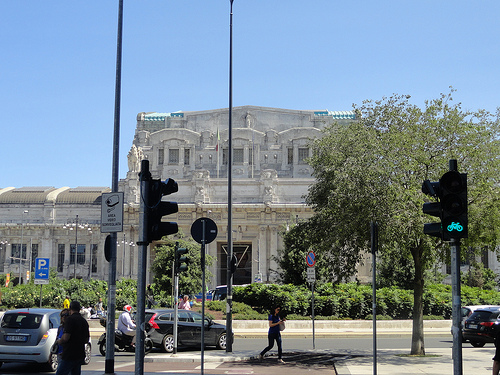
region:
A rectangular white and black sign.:
[98, 188, 129, 234]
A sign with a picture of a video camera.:
[95, 188, 125, 236]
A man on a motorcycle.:
[95, 305, 153, 357]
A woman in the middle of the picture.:
[255, 299, 299, 369]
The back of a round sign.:
[189, 210, 224, 250]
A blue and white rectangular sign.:
[31, 252, 48, 287]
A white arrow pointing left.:
[30, 260, 53, 284]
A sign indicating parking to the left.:
[27, 255, 49, 287]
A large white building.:
[3, 80, 490, 290]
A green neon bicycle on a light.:
[438, 211, 468, 238]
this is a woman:
[211, 281, 299, 334]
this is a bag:
[263, 276, 306, 367]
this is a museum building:
[213, 108, 271, 188]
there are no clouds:
[45, 109, 66, 122]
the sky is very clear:
[7, 97, 74, 172]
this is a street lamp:
[408, 155, 471, 232]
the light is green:
[434, 179, 481, 304]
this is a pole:
[410, 281, 490, 323]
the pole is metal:
[389, 304, 464, 371]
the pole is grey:
[431, 291, 468, 298]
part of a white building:
[1, 109, 378, 293]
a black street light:
[138, 165, 184, 252]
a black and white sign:
[98, 193, 123, 235]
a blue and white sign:
[30, 254, 50, 287]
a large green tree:
[306, 113, 498, 361]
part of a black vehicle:
[466, 305, 498, 344]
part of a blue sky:
[305, 0, 481, 58]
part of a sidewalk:
[330, 344, 499, 374]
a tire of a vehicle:
[217, 331, 235, 350]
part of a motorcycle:
[99, 325, 138, 355]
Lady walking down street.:
[11, 314, 498, 374]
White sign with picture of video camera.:
[100, 189, 130, 238]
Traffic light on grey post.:
[420, 150, 472, 374]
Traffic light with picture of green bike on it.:
[421, 158, 485, 374]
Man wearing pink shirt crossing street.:
[2, 292, 497, 374]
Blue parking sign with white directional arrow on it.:
[31, 254, 52, 288]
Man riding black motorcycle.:
[98, 300, 158, 355]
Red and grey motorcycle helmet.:
[120, 297, 140, 316]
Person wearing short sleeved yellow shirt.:
[63, 290, 73, 311]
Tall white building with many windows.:
[0, 97, 495, 314]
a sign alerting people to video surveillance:
[88, 184, 130, 240]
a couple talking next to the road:
[47, 294, 91, 374]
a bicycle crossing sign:
[408, 152, 478, 247]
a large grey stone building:
[8, 92, 499, 351]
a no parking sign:
[294, 245, 320, 298]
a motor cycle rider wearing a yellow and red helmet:
[110, 299, 144, 356]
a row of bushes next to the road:
[2, 268, 497, 330]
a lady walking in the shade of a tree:
[249, 292, 300, 365]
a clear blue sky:
[1, 1, 493, 187]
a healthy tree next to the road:
[288, 89, 493, 374]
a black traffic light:
[144, 169, 184, 245]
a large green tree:
[276, 90, 498, 352]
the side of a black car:
[131, 308, 231, 352]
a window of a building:
[227, 146, 249, 163]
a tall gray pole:
[135, 246, 150, 372]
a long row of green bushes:
[234, 279, 497, 320]